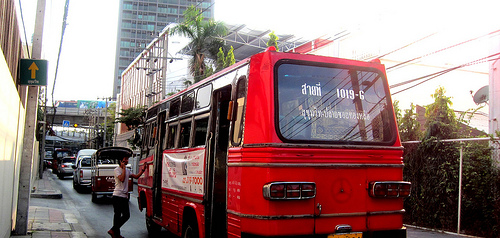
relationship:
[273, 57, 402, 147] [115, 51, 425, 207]
windshield on bus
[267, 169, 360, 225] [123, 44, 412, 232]
brake light on bus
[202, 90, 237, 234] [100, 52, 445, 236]
door on bus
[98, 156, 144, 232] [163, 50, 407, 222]
person next to bus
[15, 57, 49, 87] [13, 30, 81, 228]
sign on wall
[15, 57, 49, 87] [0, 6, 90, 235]
sign on building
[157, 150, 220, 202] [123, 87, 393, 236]
sign on bus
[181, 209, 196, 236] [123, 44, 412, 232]
tire on bus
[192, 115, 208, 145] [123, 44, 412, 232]
window on bus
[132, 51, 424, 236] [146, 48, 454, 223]
window on bus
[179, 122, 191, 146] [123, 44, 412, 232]
window on bus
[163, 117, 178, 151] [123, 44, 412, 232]
window on bus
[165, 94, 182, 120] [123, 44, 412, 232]
window on bus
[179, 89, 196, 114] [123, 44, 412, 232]
window on bus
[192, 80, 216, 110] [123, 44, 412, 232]
window on bus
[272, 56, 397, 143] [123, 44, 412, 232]
window on bus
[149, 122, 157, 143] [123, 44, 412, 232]
window on bus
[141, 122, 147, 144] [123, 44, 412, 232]
window on bus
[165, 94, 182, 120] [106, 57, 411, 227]
window on bus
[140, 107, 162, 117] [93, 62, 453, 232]
window on bus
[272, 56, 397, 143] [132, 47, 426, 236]
window on bus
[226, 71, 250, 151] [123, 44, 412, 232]
window on bus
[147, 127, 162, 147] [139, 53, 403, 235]
window on bus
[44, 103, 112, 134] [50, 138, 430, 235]
bridge across road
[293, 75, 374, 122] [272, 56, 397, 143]
writing on window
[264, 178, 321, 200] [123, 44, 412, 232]
light on bus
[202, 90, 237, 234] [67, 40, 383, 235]
door on bus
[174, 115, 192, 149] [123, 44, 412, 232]
window on bus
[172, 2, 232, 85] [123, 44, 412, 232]
palm tree by bus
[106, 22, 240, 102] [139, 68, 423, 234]
building by bus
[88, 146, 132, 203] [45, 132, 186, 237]
car on road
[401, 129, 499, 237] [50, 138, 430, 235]
greentree by road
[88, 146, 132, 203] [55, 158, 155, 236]
car on road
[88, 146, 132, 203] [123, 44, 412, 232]
car by bus